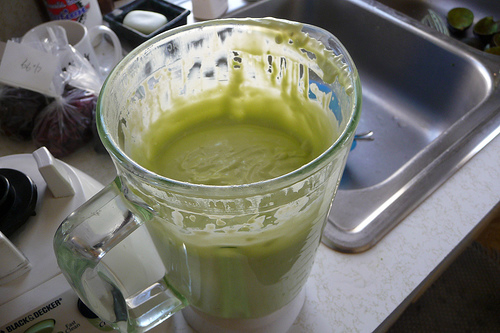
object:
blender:
[1, 146, 125, 331]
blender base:
[1, 146, 142, 331]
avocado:
[435, 4, 496, 61]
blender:
[86, 176, 336, 321]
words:
[6, 296, 75, 328]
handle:
[50, 175, 185, 331]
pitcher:
[52, 15, 363, 331]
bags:
[2, 26, 99, 145]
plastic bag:
[15, 37, 107, 160]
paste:
[205, 117, 249, 156]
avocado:
[200, 126, 282, 162]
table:
[2, 50, 497, 323]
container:
[106, 5, 202, 51]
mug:
[11, 4, 68, 56]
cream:
[151, 114, 382, 244]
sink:
[220, 0, 499, 254]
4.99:
[19, 58, 42, 74]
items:
[2, 86, 49, 144]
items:
[67, 86, 97, 145]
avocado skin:
[440, 1, 476, 41]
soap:
[117, 5, 172, 37]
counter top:
[0, 1, 480, 330]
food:
[4, 85, 97, 157]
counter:
[1, 137, 498, 331]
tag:
[1, 38, 61, 98]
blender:
[49, 12, 366, 328]